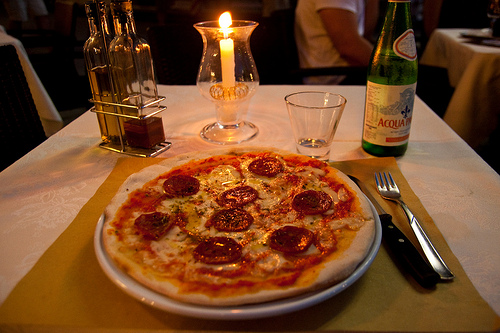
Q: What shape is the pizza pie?
A: Round.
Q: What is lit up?
A: A candle.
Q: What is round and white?
A: Plate.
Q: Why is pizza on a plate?
A: To be eaten.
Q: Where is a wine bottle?
A: On table.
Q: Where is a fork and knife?
A: To the right of the plate.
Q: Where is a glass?
A: On the table.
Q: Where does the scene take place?
A: In a restaurant.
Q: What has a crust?
A: The pizza.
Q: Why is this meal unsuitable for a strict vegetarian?
A: There is pepperoni.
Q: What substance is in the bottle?
A: Water.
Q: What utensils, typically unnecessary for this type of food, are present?
A: Fork and knife.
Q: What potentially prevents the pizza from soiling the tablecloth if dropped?
A: Placemat.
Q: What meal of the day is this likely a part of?
A: Dinner.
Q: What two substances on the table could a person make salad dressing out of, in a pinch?
A: Oil and Vinegar.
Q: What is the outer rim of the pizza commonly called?
A: The crust.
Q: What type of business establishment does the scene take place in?
A: A restaurant.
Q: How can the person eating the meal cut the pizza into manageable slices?
A: Using the knife.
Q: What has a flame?
A: Candle.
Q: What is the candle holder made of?
A: Glass.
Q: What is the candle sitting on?
A: Table.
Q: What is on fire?
A: Candle wick.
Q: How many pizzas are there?
A: One.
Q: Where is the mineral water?
A: In the green bottle.